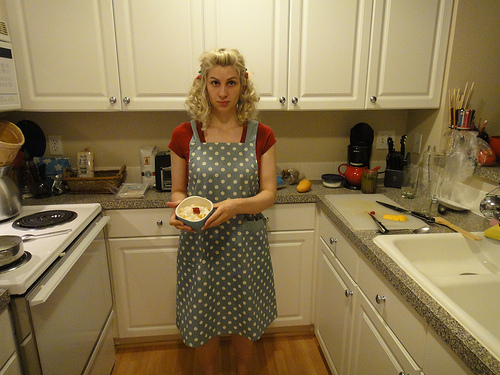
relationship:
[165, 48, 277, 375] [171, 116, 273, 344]
blond woman on apron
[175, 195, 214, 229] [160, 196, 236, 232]
bowl on hands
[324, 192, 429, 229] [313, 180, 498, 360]
cutting board on counter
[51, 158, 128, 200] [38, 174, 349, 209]
basket on counter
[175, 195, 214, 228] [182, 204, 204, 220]
bowl on food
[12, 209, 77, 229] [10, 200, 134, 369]
black burner on stove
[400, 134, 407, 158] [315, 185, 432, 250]
knife on cutting board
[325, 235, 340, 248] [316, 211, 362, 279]
knob on drawer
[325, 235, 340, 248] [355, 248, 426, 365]
knob on drawer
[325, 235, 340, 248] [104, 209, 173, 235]
knob on drawer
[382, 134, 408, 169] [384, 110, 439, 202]
knife in corner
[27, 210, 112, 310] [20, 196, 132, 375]
handle on door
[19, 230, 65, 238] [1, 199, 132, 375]
spoon on stove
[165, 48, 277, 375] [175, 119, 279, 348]
blond woman wearing apron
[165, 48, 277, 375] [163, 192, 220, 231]
blond woman holding bowl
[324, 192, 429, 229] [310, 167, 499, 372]
cutting board on counter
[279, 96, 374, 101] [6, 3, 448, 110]
metal knobs on cabinets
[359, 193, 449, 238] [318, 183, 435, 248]
knife on cutting board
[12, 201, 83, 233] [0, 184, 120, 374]
black burner on stove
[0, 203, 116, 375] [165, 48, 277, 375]
stove by blond woman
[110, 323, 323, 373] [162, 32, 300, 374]
floor under woman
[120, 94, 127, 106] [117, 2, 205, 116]
knob on cabinet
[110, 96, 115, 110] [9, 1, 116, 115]
knob on cabinet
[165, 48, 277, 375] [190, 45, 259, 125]
blond woman has blonde hair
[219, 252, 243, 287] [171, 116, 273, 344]
dots on an apron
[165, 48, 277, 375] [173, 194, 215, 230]
blond woman holding bowl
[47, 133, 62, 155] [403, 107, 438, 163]
outlet on wall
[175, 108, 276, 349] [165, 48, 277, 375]
apron on blond woman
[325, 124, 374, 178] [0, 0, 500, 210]
coffee maker in background